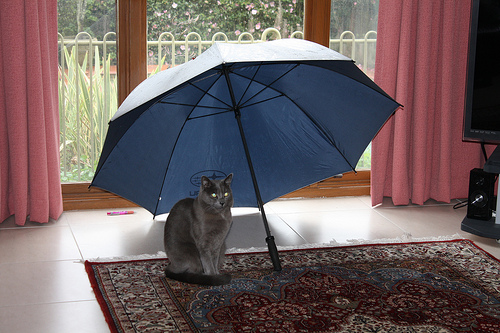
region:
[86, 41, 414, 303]
the cat is sitting under an umbrella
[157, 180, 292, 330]
he is sitting on an oriental rug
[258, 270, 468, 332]
the oriental rug is dark red with other colors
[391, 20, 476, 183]
the curtains are of pinkish red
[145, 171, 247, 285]
the cat is dark grey in color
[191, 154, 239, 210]
the cat's eyes appear to glow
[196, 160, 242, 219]
the cat's eyes are green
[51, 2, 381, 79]
an ornamental fence is in the background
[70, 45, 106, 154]
it appears there is a flower garden outside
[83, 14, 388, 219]
the umbrella appears to be blue, white & black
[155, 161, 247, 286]
a black car under an umbrella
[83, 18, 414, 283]
a blue umbrella indoors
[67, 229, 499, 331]
Persian Carpet on the floor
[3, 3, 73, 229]
pink curtain on left of door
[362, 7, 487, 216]
pink curtain on right side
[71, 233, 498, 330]
persian rug is red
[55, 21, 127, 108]
a fence outside of home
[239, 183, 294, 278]
handle of umbrella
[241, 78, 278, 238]
shaft of umbrellas is black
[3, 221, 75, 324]
shadow on the floor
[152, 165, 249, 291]
furry grey cat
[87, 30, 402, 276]
large opened navy umbrella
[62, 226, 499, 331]
beautiful ornate oriental carpet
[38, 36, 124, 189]
tall leafy plants outside the window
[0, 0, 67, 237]
long salmon colored curtain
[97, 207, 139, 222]
pink marker with orange cap on the floor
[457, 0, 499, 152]
large flat screen television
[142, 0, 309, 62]
large flowering bush outside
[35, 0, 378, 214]
large wood framed window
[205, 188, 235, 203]
glowing green cat eyes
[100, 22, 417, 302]
black cat sitting under blue umbrella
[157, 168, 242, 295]
cat sitting on oriental rug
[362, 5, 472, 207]
pink curtains surrounding windows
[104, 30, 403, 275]
blue umbrella oped up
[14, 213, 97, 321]
white square tile floor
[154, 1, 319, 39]
busj with pink flowers in the background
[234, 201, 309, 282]
black handle of umbrella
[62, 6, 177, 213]
ligh wooden frame surrounding windows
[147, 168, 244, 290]
black cat with tail wrapped around legs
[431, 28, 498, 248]
black flat screen tv and speakers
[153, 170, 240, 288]
gray cat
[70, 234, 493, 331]
red, patterned oriental rug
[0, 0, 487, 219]
long, pink curtains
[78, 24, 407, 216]
open, blue umbrella on the floor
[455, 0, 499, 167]
black, flat screen TV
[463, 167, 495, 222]
black stereo speaker on the floor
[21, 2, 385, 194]
glass door with wood trim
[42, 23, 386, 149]
white fence outside window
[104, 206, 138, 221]
pink marker on the floor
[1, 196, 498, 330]
white tile floor under the rug